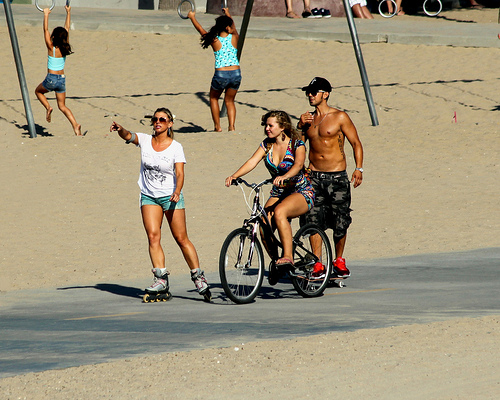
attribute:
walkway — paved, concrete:
[8, 247, 496, 365]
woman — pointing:
[105, 103, 216, 302]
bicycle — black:
[215, 171, 338, 308]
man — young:
[293, 72, 369, 290]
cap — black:
[297, 74, 337, 92]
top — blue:
[210, 30, 244, 71]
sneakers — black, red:
[312, 257, 353, 279]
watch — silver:
[354, 163, 367, 174]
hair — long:
[225, 106, 313, 189]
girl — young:
[2, 4, 404, 127]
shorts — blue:
[137, 191, 185, 211]